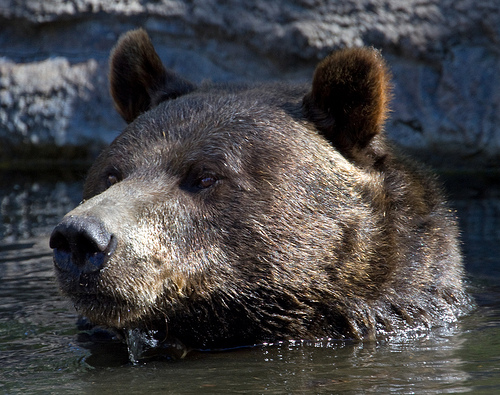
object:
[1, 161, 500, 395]
water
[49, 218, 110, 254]
nose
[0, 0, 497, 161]
wall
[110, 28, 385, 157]
ear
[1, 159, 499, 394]
river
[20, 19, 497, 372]
bear swimming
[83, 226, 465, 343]
fur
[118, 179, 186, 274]
sun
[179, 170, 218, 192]
eye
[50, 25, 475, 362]
bear's head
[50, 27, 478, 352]
bear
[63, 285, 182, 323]
mouth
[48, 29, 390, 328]
head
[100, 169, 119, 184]
eyes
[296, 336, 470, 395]
reflection